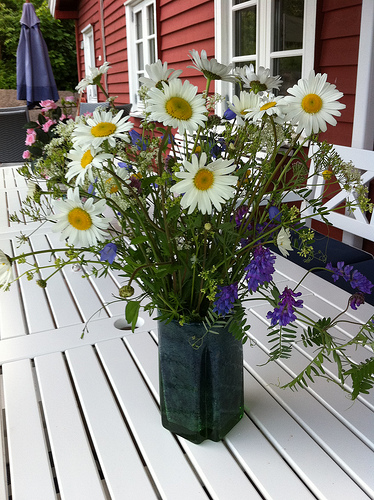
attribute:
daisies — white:
[46, 42, 362, 275]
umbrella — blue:
[13, 1, 59, 103]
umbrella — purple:
[15, 1, 57, 107]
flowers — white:
[135, 60, 208, 136]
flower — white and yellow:
[70, 111, 135, 151]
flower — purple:
[212, 284, 239, 315]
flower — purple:
[244, 242, 275, 292]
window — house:
[138, 35, 150, 91]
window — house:
[230, 36, 301, 93]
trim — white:
[126, 34, 160, 112]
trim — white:
[211, 34, 317, 146]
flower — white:
[280, 67, 348, 138]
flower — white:
[142, 75, 211, 134]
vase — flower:
[156, 302, 245, 445]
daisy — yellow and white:
[162, 146, 247, 222]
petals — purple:
[254, 274, 263, 279]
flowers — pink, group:
[29, 100, 67, 151]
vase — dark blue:
[141, 299, 259, 453]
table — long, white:
[9, 147, 356, 477]